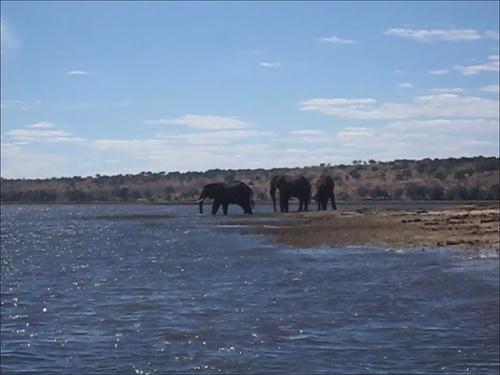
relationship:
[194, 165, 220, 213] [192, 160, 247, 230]
head of elephant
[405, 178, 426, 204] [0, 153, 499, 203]
tree in field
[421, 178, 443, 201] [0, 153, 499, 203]
tree in field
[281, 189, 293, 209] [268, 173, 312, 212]
grey leg of elephant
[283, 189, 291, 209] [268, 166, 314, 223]
grey leg of elephant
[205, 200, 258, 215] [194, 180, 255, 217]
legs of an elephant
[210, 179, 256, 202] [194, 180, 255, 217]
body of an elephant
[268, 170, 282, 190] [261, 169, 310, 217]
head of an elephant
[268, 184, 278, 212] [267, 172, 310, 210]
trunk of an elephant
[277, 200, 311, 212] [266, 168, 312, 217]
legs of an elephant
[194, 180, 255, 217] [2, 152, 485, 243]
elephant on field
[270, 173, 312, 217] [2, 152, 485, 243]
elephant on field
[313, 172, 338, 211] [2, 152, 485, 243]
elephant on field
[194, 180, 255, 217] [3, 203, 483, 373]
elephant by water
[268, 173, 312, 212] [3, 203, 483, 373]
elephant by water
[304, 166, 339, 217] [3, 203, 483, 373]
elephant by water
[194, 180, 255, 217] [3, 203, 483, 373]
elephant stepping into water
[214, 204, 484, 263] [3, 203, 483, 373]
shore next to water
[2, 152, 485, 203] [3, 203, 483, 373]
hill across water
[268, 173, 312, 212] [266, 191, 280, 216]
elephant has trunk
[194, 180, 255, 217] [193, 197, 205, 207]
elephant has tusk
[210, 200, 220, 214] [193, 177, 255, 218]
legs on elephant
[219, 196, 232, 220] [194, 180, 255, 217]
leg on elephant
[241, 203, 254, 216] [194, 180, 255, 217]
leg on elephant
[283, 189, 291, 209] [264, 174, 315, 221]
grey leg on elephant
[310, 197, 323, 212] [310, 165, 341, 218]
leg on elephant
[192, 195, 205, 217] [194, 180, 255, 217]
trunk on elephant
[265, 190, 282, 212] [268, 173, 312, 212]
trunk on elephant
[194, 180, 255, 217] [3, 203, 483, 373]
elephant near water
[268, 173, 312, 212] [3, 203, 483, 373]
elephant near water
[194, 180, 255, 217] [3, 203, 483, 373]
elephant walking in water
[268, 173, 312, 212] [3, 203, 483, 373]
elephant walking in water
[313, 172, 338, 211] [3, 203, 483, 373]
elephant walking in water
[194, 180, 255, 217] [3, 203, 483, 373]
elephant standing in water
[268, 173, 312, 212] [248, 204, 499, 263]
elephant standing on shore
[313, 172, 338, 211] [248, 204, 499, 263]
elephant standing on shore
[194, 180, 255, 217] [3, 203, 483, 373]
elephant drinking from water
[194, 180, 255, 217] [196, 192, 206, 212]
elephant has trunk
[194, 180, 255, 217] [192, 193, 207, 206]
elephant has tusk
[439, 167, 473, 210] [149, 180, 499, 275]
tree in field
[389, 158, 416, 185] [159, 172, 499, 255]
tree in field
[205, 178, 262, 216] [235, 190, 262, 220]
elephant has leg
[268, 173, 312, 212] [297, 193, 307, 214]
elephant has leg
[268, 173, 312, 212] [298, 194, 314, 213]
elephant has leg